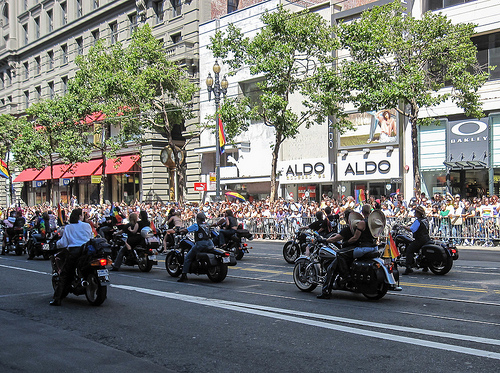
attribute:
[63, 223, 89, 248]
shirt — white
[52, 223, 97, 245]
shirt — long , white 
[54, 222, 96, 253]
shirt — long sleeved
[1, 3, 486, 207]
trees — background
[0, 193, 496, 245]
crowd — large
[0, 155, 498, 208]
street — city street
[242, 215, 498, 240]
fence — metal, silver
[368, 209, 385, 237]
hat — brown, large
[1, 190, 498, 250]
crowd — big 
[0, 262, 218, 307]
line — white 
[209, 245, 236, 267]
light — back light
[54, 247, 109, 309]
cycle — red 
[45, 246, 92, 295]
pants — black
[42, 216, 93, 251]
shirt — white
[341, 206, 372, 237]
hat — cowboy hat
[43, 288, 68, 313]
shoes — black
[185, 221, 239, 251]
vest — leather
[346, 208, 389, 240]
hats — Mexican style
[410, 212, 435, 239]
vest — leather